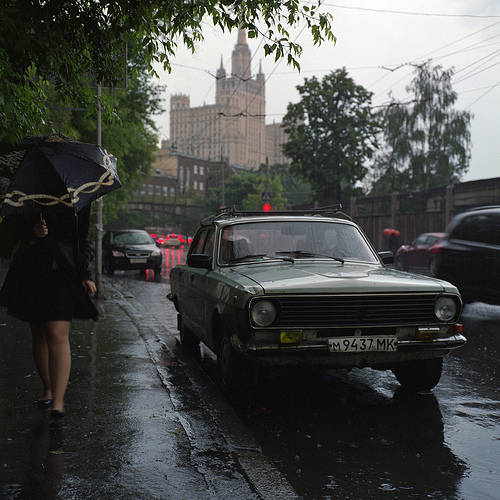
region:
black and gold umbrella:
[4, 132, 121, 229]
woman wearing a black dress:
[2, 133, 104, 422]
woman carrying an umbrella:
[0, 131, 123, 421]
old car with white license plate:
[170, 203, 467, 395]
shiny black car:
[102, 226, 163, 279]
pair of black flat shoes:
[32, 388, 66, 422]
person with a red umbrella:
[381, 223, 403, 253]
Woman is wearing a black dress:
[1, 202, 105, 327]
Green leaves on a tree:
[279, 66, 385, 200]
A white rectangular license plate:
[325, 333, 400, 355]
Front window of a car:
[217, 220, 381, 266]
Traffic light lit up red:
[257, 196, 275, 219]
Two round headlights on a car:
[249, 291, 463, 330]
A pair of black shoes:
[35, 391, 67, 423]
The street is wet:
[116, 246, 498, 497]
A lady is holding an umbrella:
[1, 134, 126, 420]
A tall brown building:
[168, 27, 296, 171]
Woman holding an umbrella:
[10, 102, 116, 436]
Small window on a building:
[189, 161, 196, 178]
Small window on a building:
[196, 164, 207, 179]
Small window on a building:
[188, 178, 196, 193]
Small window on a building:
[198, 179, 208, 192]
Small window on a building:
[168, 186, 176, 199]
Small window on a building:
[160, 182, 170, 198]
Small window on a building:
[155, 183, 160, 204]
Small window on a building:
[143, 179, 154, 194]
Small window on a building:
[226, 128, 242, 141]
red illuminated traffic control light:
[258, 188, 273, 213]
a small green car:
[167, 213, 466, 394]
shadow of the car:
[195, 351, 472, 498]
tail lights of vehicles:
[148, 229, 193, 249]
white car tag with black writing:
[327, 337, 394, 354]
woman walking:
[3, 139, 120, 424]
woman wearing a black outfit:
[1, 130, 123, 422]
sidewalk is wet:
[0, 267, 300, 497]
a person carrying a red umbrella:
[380, 224, 399, 254]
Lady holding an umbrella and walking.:
[0, 131, 119, 420]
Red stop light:
[260, 200, 274, 214]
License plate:
[324, 335, 401, 353]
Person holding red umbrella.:
[382, 225, 403, 252]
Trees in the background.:
[277, 60, 475, 194]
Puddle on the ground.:
[281, 390, 498, 499]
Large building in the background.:
[165, 9, 306, 169]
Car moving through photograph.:
[429, 204, 497, 307]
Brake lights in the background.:
[145, 226, 194, 246]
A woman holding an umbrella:
[1, 132, 125, 420]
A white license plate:
[323, 333, 399, 356]